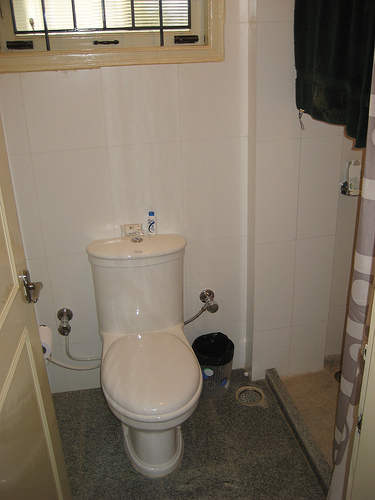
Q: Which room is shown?
A: It is a bathroom.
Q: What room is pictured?
A: It is a bathroom.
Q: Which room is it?
A: It is a bathroom.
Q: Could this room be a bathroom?
A: Yes, it is a bathroom.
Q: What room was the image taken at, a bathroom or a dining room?
A: It was taken at a bathroom.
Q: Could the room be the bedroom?
A: No, it is the bathroom.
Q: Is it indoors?
A: Yes, it is indoors.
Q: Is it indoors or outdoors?
A: It is indoors.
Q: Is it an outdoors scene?
A: No, it is indoors.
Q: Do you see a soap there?
A: No, there are no soaps.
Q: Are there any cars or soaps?
A: No, there are no soaps or cars.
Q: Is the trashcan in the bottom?
A: Yes, the trashcan is in the bottom of the image.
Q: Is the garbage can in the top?
A: No, the garbage can is in the bottom of the image.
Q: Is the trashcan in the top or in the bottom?
A: The trashcan is in the bottom of the image.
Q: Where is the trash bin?
A: The trash bin is in the bathroom.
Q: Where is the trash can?
A: The trash bin is in the bathroom.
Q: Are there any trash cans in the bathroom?
A: Yes, there is a trash can in the bathroom.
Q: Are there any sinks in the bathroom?
A: No, there is a trash can in the bathroom.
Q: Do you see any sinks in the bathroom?
A: No, there is a trash can in the bathroom.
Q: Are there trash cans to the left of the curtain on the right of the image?
A: Yes, there is a trash can to the left of the curtain.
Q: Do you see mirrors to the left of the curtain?
A: No, there is a trash can to the left of the curtain.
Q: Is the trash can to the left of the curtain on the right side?
A: Yes, the trash can is to the left of the curtain.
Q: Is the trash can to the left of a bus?
A: No, the trash can is to the left of the curtain.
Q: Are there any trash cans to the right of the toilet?
A: Yes, there is a trash can to the right of the toilet.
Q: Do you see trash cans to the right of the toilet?
A: Yes, there is a trash can to the right of the toilet.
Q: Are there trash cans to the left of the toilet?
A: No, the trash can is to the right of the toilet.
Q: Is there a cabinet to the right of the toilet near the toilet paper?
A: No, there is a trash can to the right of the toilet.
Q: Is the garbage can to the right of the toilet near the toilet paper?
A: Yes, the garbage can is to the right of the toilet.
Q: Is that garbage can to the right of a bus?
A: No, the garbage can is to the right of the toilet.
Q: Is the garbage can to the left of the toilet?
A: No, the garbage can is to the right of the toilet.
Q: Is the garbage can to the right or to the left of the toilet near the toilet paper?
A: The garbage can is to the right of the toilet.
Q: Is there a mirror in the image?
A: No, there are no mirrors.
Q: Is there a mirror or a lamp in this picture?
A: No, there are no mirrors or lamps.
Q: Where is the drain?
A: The drain is on the floor.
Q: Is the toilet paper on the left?
A: Yes, the toilet paper is on the left of the image.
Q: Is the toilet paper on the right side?
A: No, the toilet paper is on the left of the image.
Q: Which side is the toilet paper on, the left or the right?
A: The toilet paper is on the left of the image.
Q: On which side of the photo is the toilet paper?
A: The toilet paper is on the left of the image.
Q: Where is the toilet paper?
A: The toilet paper is in the bathroom.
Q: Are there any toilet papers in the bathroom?
A: Yes, there is a toilet paper in the bathroom.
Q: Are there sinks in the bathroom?
A: No, there is a toilet paper in the bathroom.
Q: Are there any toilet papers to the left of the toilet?
A: Yes, there is a toilet paper to the left of the toilet.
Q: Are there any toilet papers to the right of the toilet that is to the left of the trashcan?
A: No, the toilet paper is to the left of the toilet.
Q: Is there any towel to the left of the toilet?
A: No, there is a toilet paper to the left of the toilet.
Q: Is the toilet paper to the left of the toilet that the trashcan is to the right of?
A: Yes, the toilet paper is to the left of the toilet.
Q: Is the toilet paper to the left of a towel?
A: No, the toilet paper is to the left of the toilet.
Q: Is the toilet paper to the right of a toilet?
A: No, the toilet paper is to the left of a toilet.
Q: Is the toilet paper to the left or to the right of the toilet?
A: The toilet paper is to the left of the toilet.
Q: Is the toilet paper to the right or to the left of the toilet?
A: The toilet paper is to the left of the toilet.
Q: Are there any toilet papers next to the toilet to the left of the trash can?
A: Yes, there is a toilet paper next to the toilet.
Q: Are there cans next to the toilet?
A: No, there is a toilet paper next to the toilet.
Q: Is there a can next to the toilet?
A: No, there is a toilet paper next to the toilet.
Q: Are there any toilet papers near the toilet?
A: Yes, there is a toilet paper near the toilet.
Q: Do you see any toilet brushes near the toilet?
A: No, there is a toilet paper near the toilet.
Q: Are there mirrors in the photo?
A: No, there are no mirrors.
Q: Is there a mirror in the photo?
A: No, there are no mirrors.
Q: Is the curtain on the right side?
A: Yes, the curtain is on the right of the image.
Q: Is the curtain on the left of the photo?
A: No, the curtain is on the right of the image.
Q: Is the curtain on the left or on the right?
A: The curtain is on the right of the image.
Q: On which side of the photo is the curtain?
A: The curtain is on the right of the image.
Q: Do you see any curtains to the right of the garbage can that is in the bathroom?
A: Yes, there is a curtain to the right of the trash can.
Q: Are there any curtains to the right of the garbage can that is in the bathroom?
A: Yes, there is a curtain to the right of the trash can.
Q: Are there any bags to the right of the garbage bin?
A: No, there is a curtain to the right of the garbage bin.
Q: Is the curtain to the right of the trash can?
A: Yes, the curtain is to the right of the trash can.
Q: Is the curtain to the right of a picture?
A: No, the curtain is to the right of the trash can.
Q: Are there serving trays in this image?
A: No, there are no serving trays.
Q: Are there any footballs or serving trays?
A: No, there are no serving trays or footballs.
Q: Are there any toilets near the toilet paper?
A: Yes, there is a toilet near the toilet paper.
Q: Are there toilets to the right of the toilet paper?
A: Yes, there is a toilet to the right of the toilet paper.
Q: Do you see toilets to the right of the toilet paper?
A: Yes, there is a toilet to the right of the toilet paper.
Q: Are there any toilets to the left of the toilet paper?
A: No, the toilet is to the right of the toilet paper.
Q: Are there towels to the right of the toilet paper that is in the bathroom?
A: No, there is a toilet to the right of the toilet paper.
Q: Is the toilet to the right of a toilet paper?
A: Yes, the toilet is to the right of a toilet paper.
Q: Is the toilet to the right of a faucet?
A: No, the toilet is to the right of a toilet paper.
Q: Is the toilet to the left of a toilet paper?
A: No, the toilet is to the right of a toilet paper.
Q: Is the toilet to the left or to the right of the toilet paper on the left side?
A: The toilet is to the right of the toilet paper.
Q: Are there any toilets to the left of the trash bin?
A: Yes, there is a toilet to the left of the trash bin.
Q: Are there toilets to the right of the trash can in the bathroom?
A: No, the toilet is to the left of the garbage bin.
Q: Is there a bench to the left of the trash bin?
A: No, there is a toilet to the left of the trash bin.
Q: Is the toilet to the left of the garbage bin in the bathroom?
A: Yes, the toilet is to the left of the trash can.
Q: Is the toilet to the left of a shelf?
A: No, the toilet is to the left of the trash can.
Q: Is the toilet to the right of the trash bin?
A: No, the toilet is to the left of the trash bin.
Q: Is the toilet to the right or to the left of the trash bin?
A: The toilet is to the left of the trash bin.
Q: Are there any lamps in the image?
A: No, there are no lamps.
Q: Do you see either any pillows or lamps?
A: No, there are no lamps or pillows.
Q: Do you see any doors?
A: Yes, there is a door.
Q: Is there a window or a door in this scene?
A: Yes, there is a door.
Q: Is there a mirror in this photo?
A: No, there are no mirrors.